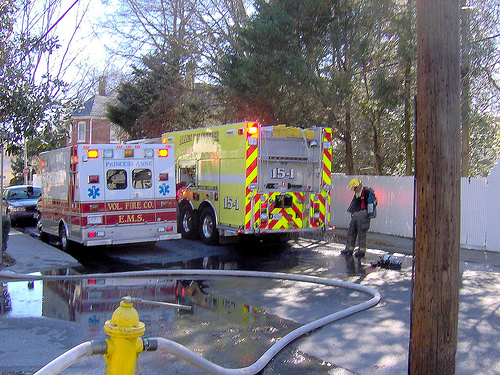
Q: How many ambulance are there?
A: One.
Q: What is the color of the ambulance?
A: White and red.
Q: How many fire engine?
A: 1.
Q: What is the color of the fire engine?
A: Yellow and red.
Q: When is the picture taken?
A: Daytime.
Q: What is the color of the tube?
A: White.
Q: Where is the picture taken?
A: On the street.